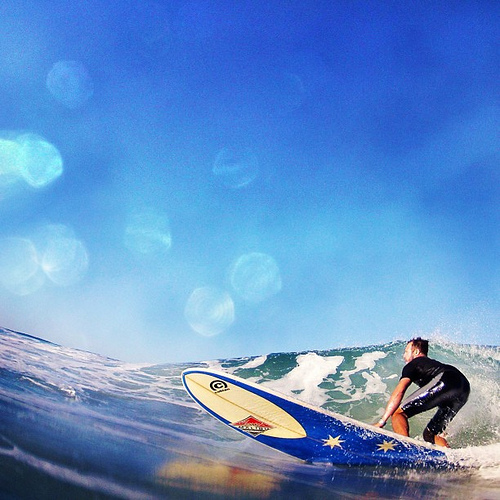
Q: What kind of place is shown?
A: It is an ocean.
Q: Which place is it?
A: It is an ocean.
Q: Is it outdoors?
A: Yes, it is outdoors.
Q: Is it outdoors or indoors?
A: It is outdoors.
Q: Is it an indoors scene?
A: No, it is outdoors.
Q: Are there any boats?
A: No, there are no boats.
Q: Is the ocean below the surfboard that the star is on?
A: Yes, the ocean is below the surf board.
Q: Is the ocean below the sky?
A: Yes, the ocean is below the sky.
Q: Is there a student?
A: No, there are no students.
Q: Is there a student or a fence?
A: No, there are no students or fences.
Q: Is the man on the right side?
A: Yes, the man is on the right of the image.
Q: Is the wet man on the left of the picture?
A: No, the man is on the right of the image.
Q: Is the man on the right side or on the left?
A: The man is on the right of the image.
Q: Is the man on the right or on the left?
A: The man is on the right of the image.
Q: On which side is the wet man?
A: The man is on the right of the image.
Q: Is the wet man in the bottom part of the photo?
A: Yes, the man is in the bottom of the image.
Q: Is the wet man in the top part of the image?
A: No, the man is in the bottom of the image.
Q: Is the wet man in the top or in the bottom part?
A: The man is in the bottom of the image.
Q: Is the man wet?
A: Yes, the man is wet.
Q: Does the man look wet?
A: Yes, the man is wet.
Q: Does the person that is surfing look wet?
A: Yes, the man is wet.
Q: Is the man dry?
A: No, the man is wet.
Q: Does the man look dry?
A: No, the man is wet.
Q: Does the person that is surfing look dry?
A: No, the man is wet.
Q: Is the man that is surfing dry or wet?
A: The man is wet.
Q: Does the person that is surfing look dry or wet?
A: The man is wet.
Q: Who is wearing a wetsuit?
A: The man is wearing a wetsuit.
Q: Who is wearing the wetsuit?
A: The man is wearing a wetsuit.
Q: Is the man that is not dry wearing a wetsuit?
A: Yes, the man is wearing a wetsuit.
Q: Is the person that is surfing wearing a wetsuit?
A: Yes, the man is wearing a wetsuit.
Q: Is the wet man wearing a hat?
A: No, the man is wearing a wetsuit.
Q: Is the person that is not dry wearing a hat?
A: No, the man is wearing a wetsuit.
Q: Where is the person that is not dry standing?
A: The man is standing in the ocean.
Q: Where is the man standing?
A: The man is standing in the ocean.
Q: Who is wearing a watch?
A: The man is wearing a watch.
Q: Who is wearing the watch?
A: The man is wearing a watch.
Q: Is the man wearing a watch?
A: Yes, the man is wearing a watch.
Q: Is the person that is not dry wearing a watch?
A: Yes, the man is wearing a watch.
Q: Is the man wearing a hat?
A: No, the man is wearing a watch.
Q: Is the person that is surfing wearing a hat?
A: No, the man is wearing a watch.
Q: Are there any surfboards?
A: Yes, there is a surfboard.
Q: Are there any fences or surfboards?
A: Yes, there is a surfboard.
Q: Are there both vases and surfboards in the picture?
A: No, there is a surfboard but no vases.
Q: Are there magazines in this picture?
A: No, there are no magazines.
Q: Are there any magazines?
A: No, there are no magazines.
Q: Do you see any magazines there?
A: No, there are no magazines.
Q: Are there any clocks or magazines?
A: No, there are no magazines or clocks.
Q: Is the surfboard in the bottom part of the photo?
A: Yes, the surfboard is in the bottom of the image.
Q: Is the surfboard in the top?
A: No, the surfboard is in the bottom of the image.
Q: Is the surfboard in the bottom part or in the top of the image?
A: The surfboard is in the bottom of the image.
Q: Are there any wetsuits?
A: Yes, there is a wetsuit.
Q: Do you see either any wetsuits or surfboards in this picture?
A: Yes, there is a wetsuit.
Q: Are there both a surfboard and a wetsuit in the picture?
A: Yes, there are both a wetsuit and a surfboard.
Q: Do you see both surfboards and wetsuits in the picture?
A: Yes, there are both a wetsuit and a surfboard.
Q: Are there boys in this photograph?
A: No, there are no boys.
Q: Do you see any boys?
A: No, there are no boys.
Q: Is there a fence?
A: No, there are no fences.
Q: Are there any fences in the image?
A: No, there are no fences.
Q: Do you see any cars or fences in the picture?
A: No, there are no fences or cars.